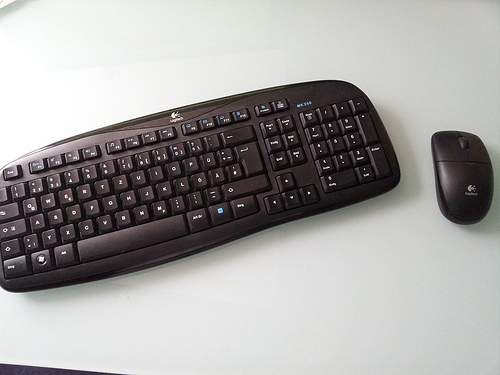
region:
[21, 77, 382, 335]
black keyboard on table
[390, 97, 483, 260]
black mouse on table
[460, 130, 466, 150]
black scroll wheel on mouse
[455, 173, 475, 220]
white logo on back of mouse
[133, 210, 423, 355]
white table beneath mouse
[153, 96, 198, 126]
logo on top of keyboard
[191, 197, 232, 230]
blue key on bottom of keyboard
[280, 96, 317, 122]
blue lettering on side of key board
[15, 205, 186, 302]
large space key on key board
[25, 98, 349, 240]
keys on board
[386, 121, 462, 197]
an optical mouse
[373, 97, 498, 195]
an optical mouse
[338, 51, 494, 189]
an optical mouse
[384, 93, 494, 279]
an optical mouse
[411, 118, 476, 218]
black mouse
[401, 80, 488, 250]
black mouse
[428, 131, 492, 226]
cordless computer mouse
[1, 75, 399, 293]
black cordless keyboard for computer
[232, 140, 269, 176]
enter button on keyboard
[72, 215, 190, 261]
spacebar on computer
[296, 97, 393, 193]
number pad area of keyboard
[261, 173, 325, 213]
arrow keys on keyboard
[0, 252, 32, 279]
control button on keyboard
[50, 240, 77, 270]
alt button on keyboard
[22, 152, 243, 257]
letter buttons on keyboard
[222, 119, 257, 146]
backspace button on keyboard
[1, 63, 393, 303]
Black wireless keyboard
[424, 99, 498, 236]
Black wireless mouse device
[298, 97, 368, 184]
Number keys on a keyboard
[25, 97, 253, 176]
Function keys on a keyboard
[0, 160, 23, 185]
Escape key on a keyboard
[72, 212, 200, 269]
Space bar on a keyboard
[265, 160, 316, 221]
Arrow keys on a keyboard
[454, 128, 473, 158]
Scroll wheel on a mouse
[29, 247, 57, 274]
Windows shortcut key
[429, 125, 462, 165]
Left mouse button